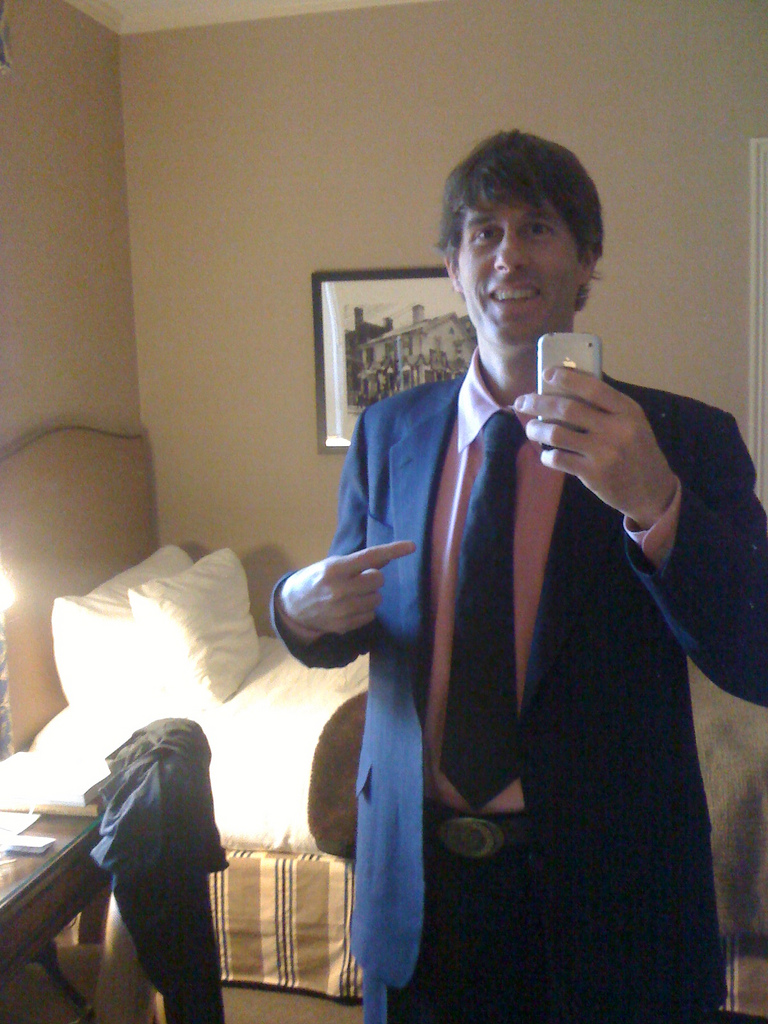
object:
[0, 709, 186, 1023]
chair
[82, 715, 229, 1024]
jacket